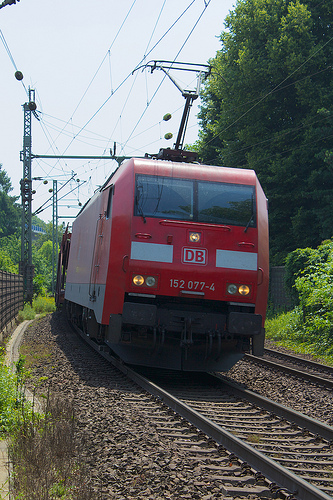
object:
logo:
[183, 248, 206, 263]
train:
[54, 156, 273, 374]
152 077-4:
[167, 278, 218, 292]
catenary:
[118, 51, 182, 154]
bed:
[258, 401, 332, 443]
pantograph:
[129, 69, 168, 127]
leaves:
[291, 118, 302, 130]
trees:
[270, 108, 333, 236]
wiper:
[134, 176, 146, 221]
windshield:
[134, 175, 195, 220]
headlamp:
[187, 229, 201, 241]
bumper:
[149, 326, 168, 353]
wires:
[87, 0, 200, 128]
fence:
[2, 273, 25, 332]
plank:
[116, 384, 156, 393]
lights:
[240, 284, 251, 294]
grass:
[289, 323, 303, 343]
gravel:
[282, 356, 294, 367]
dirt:
[74, 414, 85, 431]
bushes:
[33, 289, 58, 315]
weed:
[39, 379, 58, 494]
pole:
[32, 151, 64, 163]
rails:
[55, 304, 330, 497]